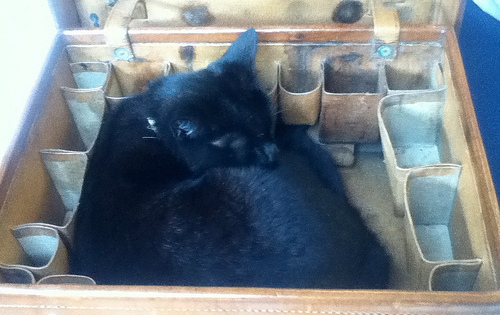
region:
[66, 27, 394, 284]
a cat laying in container.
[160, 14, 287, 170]
the head of a black cat.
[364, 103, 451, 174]
a divider in a case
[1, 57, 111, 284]
a row of a case.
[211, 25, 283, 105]
an ear of a black cat.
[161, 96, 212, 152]
a cat's right ear.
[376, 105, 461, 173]
a divider in a brown case.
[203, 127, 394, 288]
a black cat laying down.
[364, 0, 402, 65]
a latch on a enclosure.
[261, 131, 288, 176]
a cat's nose.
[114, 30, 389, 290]
the cat is in the suit case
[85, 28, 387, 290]
the cat is black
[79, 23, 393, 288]
the cat is curled up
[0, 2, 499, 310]
the case is brown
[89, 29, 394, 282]
the cat is sleeping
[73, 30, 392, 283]
the cat is large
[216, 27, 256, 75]
the cat has a pointy ear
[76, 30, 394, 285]
the cat is comfortable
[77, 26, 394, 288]
the cat has a shiny coat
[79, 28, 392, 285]
the cat is laying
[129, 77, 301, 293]
this is a cat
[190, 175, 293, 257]
the cat is black in color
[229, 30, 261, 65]
this is the ear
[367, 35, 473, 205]
this is a bag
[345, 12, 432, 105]
the bag is open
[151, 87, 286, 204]
the cat is sleeping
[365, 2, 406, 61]
this is the hinge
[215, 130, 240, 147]
the eye is closed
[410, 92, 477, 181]
the bag is brown in color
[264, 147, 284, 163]
this is the nose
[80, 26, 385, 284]
curled up sleeping cat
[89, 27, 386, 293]
sleeping black cat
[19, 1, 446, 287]
black cat sleeping in old case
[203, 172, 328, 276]
black cat fur reflecting light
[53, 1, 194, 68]
old leather hinge on case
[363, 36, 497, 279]
storage pocket in old leather case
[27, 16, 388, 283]
black cat sleeping in case with storage pockets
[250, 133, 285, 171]
nose of a black cat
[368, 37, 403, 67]
metal attachment with green oxidation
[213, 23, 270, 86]
left ear of a black cat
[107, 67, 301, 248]
the cat is black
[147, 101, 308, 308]
the cat is black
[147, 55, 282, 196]
the cat is black